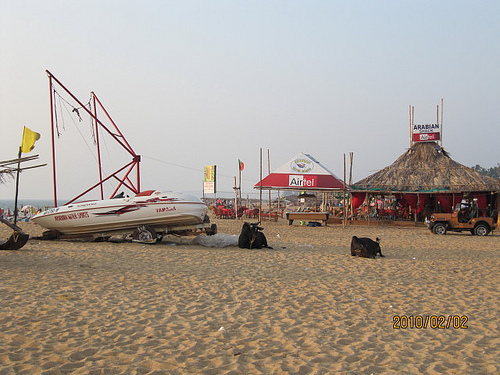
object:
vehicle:
[430, 200, 495, 234]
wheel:
[133, 228, 154, 242]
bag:
[351, 236, 379, 258]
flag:
[21, 128, 38, 152]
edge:
[349, 184, 498, 194]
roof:
[351, 144, 500, 192]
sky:
[1, 0, 500, 181]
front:
[32, 205, 58, 230]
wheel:
[471, 221, 489, 236]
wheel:
[431, 222, 446, 234]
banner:
[413, 124, 440, 141]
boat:
[31, 192, 206, 234]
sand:
[140, 291, 329, 362]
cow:
[239, 221, 268, 249]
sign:
[289, 175, 318, 186]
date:
[393, 315, 468, 329]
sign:
[204, 164, 215, 193]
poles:
[409, 102, 412, 148]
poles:
[343, 154, 345, 225]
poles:
[260, 149, 262, 221]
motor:
[236, 221, 266, 249]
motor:
[350, 231, 390, 259]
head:
[243, 221, 263, 240]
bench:
[0, 217, 499, 375]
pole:
[14, 146, 23, 223]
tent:
[259, 153, 351, 188]